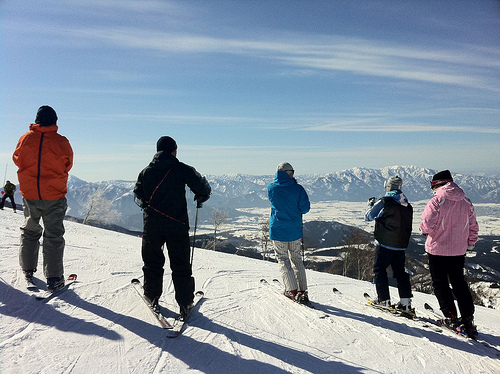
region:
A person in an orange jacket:
[12, 101, 82, 243]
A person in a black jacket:
[107, 98, 227, 294]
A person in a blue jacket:
[260, 147, 325, 265]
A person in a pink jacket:
[425, 167, 499, 294]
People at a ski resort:
[3, 66, 498, 338]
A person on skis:
[14, 92, 96, 319]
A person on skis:
[119, 111, 240, 356]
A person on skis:
[252, 147, 331, 332]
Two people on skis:
[350, 142, 476, 372]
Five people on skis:
[21, 105, 486, 345]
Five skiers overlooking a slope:
[8, 127, 483, 347]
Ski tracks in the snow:
[165, 255, 295, 360]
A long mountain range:
[71, 155, 491, 210]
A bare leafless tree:
[205, 208, 230, 250]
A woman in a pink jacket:
[421, 174, 479, 259]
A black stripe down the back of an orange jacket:
[9, 112, 96, 199]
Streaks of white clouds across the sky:
[238, 29, 492, 73]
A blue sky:
[69, 54, 239, 102]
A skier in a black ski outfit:
[132, 122, 214, 322]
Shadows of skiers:
[60, 272, 299, 370]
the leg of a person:
[43, 192, 73, 289]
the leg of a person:
[10, 192, 42, 284]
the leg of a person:
[163, 220, 200, 317]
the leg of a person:
[138, 219, 175, 322]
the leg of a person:
[271, 232, 301, 303]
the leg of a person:
[287, 220, 315, 299]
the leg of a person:
[367, 248, 395, 311]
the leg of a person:
[393, 256, 417, 313]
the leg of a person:
[431, 265, 458, 331]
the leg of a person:
[447, 258, 482, 346]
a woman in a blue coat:
[264, 161, 316, 303]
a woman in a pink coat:
[417, 170, 479, 337]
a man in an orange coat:
[11, 103, 78, 300]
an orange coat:
[10, 122, 75, 202]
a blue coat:
[267, 167, 311, 240]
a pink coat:
[420, 180, 480, 254]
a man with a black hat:
[130, 133, 212, 338]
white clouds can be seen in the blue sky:
[0, 0, 499, 102]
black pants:
[426, 255, 474, 315]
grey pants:
[17, 199, 67, 269]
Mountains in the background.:
[10, 156, 488, 220]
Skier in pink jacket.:
[422, 168, 481, 263]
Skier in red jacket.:
[11, 103, 80, 294]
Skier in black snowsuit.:
[133, 131, 218, 336]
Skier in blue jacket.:
[268, 157, 318, 307]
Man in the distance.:
[2, 173, 16, 213]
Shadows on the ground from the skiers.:
[3, 266, 493, 372]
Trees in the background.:
[80, 188, 495, 305]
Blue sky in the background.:
[0, 1, 498, 182]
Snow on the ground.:
[0, 202, 499, 367]